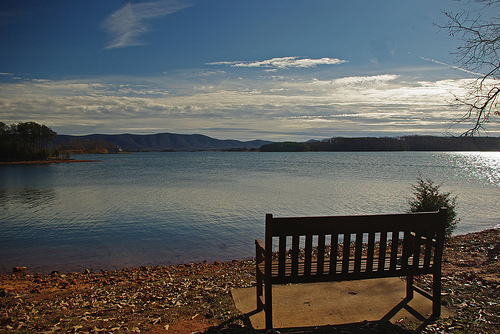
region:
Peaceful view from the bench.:
[5, 7, 490, 219]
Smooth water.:
[5, 147, 492, 232]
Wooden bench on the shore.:
[245, 206, 455, 326]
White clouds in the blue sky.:
[5, 46, 495, 118]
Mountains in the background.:
[57, 125, 268, 155]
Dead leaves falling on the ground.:
[5, 250, 231, 325]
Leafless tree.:
[432, 0, 497, 136]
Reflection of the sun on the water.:
[447, 143, 497, 190]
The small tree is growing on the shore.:
[405, 170, 455, 240]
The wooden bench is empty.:
[247, 210, 452, 320]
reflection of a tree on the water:
[14, 186, 61, 221]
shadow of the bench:
[199, 289, 443, 330]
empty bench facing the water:
[234, 207, 455, 323]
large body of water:
[0, 141, 499, 250]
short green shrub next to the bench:
[406, 172, 461, 256]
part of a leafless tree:
[434, 4, 498, 156]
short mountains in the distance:
[62, 126, 274, 153]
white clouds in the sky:
[11, 64, 498, 132]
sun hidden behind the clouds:
[344, 70, 479, 121]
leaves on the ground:
[10, 276, 218, 322]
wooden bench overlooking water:
[242, 203, 448, 327]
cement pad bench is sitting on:
[234, 267, 448, 320]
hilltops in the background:
[74, 132, 491, 161]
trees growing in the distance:
[5, 115, 65, 161]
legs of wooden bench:
[248, 276, 451, 323]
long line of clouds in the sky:
[14, 55, 493, 123]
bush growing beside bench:
[401, 173, 458, 238]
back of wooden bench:
[268, 213, 438, 272]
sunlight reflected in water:
[443, 140, 499, 177]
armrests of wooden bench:
[251, 233, 438, 264]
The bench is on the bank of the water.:
[0, 137, 499, 332]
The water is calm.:
[0, 134, 499, 291]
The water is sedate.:
[1, 138, 498, 317]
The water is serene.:
[1, 133, 498, 323]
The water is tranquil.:
[0, 133, 498, 320]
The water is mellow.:
[0, 126, 499, 316]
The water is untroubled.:
[0, 128, 498, 317]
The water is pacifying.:
[1, 127, 498, 311]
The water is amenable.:
[1, 133, 499, 324]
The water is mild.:
[0, 127, 499, 319]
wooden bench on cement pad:
[245, 201, 450, 332]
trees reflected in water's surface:
[1, 177, 58, 218]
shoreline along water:
[11, 226, 491, 332]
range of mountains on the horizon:
[63, 125, 493, 152]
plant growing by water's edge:
[399, 170, 459, 238]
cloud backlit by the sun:
[297, 60, 479, 133]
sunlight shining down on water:
[442, 140, 498, 182]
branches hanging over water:
[454, 37, 494, 134]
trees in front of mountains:
[6, 116, 70, 170]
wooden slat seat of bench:
[254, 245, 438, 275]